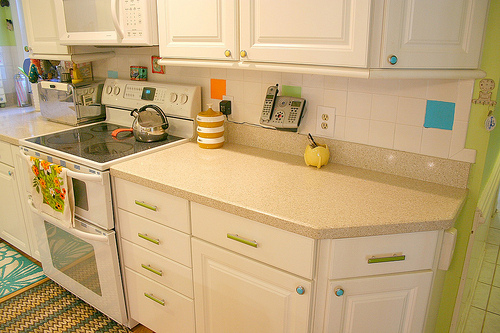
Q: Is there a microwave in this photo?
A: Yes, there is a microwave.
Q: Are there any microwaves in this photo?
A: Yes, there is a microwave.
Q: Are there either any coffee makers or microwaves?
A: Yes, there is a microwave.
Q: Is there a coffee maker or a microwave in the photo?
A: Yes, there is a microwave.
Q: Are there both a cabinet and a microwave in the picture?
A: Yes, there are both a microwave and a cabinet.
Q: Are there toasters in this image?
A: No, there are no toasters.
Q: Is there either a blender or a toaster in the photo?
A: No, there are no toasters or blenders.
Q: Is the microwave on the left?
A: Yes, the microwave is on the left of the image.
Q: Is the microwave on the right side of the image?
A: No, the microwave is on the left of the image.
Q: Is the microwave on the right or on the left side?
A: The microwave is on the left of the image.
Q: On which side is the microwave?
A: The microwave is on the left of the image.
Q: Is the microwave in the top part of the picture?
A: Yes, the microwave is in the top of the image.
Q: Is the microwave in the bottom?
A: No, the microwave is in the top of the image.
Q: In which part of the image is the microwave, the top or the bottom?
A: The microwave is in the top of the image.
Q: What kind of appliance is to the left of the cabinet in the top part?
A: The appliance is a microwave.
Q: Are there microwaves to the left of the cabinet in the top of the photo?
A: Yes, there is a microwave to the left of the cabinet.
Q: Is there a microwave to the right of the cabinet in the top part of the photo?
A: No, the microwave is to the left of the cabinet.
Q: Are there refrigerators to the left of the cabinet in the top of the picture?
A: No, there is a microwave to the left of the cabinet.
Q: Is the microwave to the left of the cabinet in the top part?
A: Yes, the microwave is to the left of the cabinet.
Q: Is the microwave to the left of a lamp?
A: No, the microwave is to the left of the cabinet.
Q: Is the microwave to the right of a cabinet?
A: No, the microwave is to the left of a cabinet.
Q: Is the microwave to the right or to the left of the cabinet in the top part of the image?
A: The microwave is to the left of the cabinet.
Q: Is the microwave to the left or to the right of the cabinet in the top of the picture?
A: The microwave is to the left of the cabinet.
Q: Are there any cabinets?
A: Yes, there is a cabinet.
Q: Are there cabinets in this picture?
A: Yes, there is a cabinet.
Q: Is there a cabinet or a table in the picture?
A: Yes, there is a cabinet.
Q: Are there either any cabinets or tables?
A: Yes, there is a cabinet.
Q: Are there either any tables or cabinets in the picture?
A: Yes, there is a cabinet.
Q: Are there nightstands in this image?
A: No, there are no nightstands.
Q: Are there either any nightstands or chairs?
A: No, there are no nightstands or chairs.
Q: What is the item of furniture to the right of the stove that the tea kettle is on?
A: The piece of furniture is a cabinet.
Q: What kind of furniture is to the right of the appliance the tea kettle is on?
A: The piece of furniture is a cabinet.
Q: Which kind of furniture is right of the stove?
A: The piece of furniture is a cabinet.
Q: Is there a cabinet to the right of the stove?
A: Yes, there is a cabinet to the right of the stove.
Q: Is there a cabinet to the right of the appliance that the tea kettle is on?
A: Yes, there is a cabinet to the right of the stove.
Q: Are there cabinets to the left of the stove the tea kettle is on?
A: No, the cabinet is to the right of the stove.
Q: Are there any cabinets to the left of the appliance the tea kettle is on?
A: No, the cabinet is to the right of the stove.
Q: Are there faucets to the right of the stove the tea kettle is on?
A: No, there is a cabinet to the right of the stove.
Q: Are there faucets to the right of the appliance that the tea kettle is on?
A: No, there is a cabinet to the right of the stove.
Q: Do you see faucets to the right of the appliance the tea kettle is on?
A: No, there is a cabinet to the right of the stove.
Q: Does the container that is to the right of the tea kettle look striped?
A: Yes, the container is striped.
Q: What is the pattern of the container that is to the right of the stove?
A: The container is striped.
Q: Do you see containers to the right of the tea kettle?
A: Yes, there is a container to the right of the tea kettle.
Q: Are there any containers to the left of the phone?
A: Yes, there is a container to the left of the phone.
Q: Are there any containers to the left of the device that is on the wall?
A: Yes, there is a container to the left of the phone.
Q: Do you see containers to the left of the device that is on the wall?
A: Yes, there is a container to the left of the phone.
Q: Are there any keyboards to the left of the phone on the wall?
A: No, there is a container to the left of the phone.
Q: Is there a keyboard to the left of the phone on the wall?
A: No, there is a container to the left of the phone.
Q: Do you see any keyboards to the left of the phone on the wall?
A: No, there is a container to the left of the phone.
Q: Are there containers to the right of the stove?
A: Yes, there is a container to the right of the stove.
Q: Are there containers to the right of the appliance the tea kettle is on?
A: Yes, there is a container to the right of the stove.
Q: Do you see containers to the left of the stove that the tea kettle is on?
A: No, the container is to the right of the stove.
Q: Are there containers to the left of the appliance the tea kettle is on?
A: No, the container is to the right of the stove.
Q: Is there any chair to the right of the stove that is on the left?
A: No, there is a container to the right of the stove.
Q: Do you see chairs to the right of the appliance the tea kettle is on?
A: No, there is a container to the right of the stove.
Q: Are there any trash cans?
A: No, there are no trash cans.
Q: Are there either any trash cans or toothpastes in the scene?
A: No, there are no trash cans or toothpastes.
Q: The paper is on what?
A: The paper is on the wall.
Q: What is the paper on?
A: The paper is on the wall.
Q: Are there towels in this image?
A: Yes, there is a towel.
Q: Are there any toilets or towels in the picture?
A: Yes, there is a towel.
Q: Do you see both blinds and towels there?
A: No, there is a towel but no blinds.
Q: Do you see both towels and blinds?
A: No, there is a towel but no blinds.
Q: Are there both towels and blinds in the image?
A: No, there is a towel but no blinds.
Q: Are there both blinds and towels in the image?
A: No, there is a towel but no blinds.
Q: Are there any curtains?
A: No, there are no curtains.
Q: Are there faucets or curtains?
A: No, there are no curtains or faucets.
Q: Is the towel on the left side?
A: Yes, the towel is on the left of the image.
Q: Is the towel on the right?
A: No, the towel is on the left of the image.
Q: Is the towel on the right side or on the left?
A: The towel is on the left of the image.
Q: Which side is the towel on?
A: The towel is on the left of the image.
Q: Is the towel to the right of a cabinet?
A: No, the towel is to the left of a cabinet.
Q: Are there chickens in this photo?
A: No, there are no chickens.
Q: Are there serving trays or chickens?
A: No, there are no chickens or serving trays.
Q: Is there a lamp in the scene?
A: No, there are no lamps.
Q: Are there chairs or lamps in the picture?
A: No, there are no lamps or chairs.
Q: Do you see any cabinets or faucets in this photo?
A: Yes, there is a cabinet.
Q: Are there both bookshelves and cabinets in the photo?
A: No, there is a cabinet but no bookshelves.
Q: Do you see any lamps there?
A: No, there are no lamps.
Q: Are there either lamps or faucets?
A: No, there are no lamps or faucets.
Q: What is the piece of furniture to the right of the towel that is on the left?
A: The piece of furniture is a cabinet.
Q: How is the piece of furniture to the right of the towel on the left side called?
A: The piece of furniture is a cabinet.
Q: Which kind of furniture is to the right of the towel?
A: The piece of furniture is a cabinet.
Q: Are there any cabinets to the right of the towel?
A: Yes, there is a cabinet to the right of the towel.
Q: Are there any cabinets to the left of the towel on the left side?
A: No, the cabinet is to the right of the towel.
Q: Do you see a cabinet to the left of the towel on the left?
A: No, the cabinet is to the right of the towel.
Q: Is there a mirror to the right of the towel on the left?
A: No, there is a cabinet to the right of the towel.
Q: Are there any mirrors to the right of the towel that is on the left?
A: No, there is a cabinet to the right of the towel.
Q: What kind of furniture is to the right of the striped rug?
A: The piece of furniture is a cabinet.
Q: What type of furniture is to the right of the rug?
A: The piece of furniture is a cabinet.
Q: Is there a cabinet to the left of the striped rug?
A: No, the cabinet is to the right of the rug.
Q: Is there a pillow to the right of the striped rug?
A: No, there is a cabinet to the right of the rug.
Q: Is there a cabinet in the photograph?
A: Yes, there is a cabinet.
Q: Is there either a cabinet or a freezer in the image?
A: Yes, there is a cabinet.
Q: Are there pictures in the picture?
A: No, there are no pictures.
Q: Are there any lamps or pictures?
A: No, there are no pictures or lamps.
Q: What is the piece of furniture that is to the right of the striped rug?
A: The piece of furniture is a cabinet.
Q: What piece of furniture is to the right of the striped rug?
A: The piece of furniture is a cabinet.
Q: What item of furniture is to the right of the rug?
A: The piece of furniture is a cabinet.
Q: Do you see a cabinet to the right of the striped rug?
A: Yes, there is a cabinet to the right of the rug.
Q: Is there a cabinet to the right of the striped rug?
A: Yes, there is a cabinet to the right of the rug.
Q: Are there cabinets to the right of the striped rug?
A: Yes, there is a cabinet to the right of the rug.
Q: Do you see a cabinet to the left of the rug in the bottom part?
A: No, the cabinet is to the right of the rug.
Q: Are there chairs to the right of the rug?
A: No, there is a cabinet to the right of the rug.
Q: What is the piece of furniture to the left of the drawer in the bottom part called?
A: The piece of furniture is a cabinet.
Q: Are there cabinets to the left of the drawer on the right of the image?
A: Yes, there is a cabinet to the left of the drawer.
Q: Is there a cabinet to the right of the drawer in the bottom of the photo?
A: No, the cabinet is to the left of the drawer.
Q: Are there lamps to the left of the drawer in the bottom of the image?
A: No, there is a cabinet to the left of the drawer.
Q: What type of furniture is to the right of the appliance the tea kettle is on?
A: The piece of furniture is a cabinet.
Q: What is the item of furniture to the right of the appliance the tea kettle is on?
A: The piece of furniture is a cabinet.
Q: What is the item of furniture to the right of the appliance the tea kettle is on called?
A: The piece of furniture is a cabinet.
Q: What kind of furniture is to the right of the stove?
A: The piece of furniture is a cabinet.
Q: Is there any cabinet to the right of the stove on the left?
A: Yes, there is a cabinet to the right of the stove.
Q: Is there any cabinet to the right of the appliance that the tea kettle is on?
A: Yes, there is a cabinet to the right of the stove.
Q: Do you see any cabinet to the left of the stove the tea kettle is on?
A: No, the cabinet is to the right of the stove.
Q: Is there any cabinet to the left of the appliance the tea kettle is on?
A: No, the cabinet is to the right of the stove.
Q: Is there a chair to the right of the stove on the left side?
A: No, there is a cabinet to the right of the stove.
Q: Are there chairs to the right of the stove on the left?
A: No, there is a cabinet to the right of the stove.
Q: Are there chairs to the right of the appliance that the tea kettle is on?
A: No, there is a cabinet to the right of the stove.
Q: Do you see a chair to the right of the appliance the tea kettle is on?
A: No, there is a cabinet to the right of the stove.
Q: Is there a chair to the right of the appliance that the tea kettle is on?
A: No, there is a cabinet to the right of the stove.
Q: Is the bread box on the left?
A: Yes, the bread box is on the left of the image.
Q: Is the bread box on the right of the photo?
A: No, the bread box is on the left of the image.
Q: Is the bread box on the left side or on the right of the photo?
A: The bread box is on the left of the image.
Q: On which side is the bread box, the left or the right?
A: The bread box is on the left of the image.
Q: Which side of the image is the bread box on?
A: The bread box is on the left of the image.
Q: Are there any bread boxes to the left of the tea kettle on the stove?
A: Yes, there is a bread box to the left of the tea kettle.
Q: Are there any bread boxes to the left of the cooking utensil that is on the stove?
A: Yes, there is a bread box to the left of the tea kettle.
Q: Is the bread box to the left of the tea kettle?
A: Yes, the bread box is to the left of the tea kettle.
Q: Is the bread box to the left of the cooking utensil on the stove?
A: Yes, the bread box is to the left of the tea kettle.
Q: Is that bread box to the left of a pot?
A: No, the bread box is to the left of the tea kettle.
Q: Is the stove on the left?
A: Yes, the stove is on the left of the image.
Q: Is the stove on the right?
A: No, the stove is on the left of the image.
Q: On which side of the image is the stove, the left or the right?
A: The stove is on the left of the image.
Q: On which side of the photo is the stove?
A: The stove is on the left of the image.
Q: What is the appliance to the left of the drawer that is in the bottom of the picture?
A: The appliance is a stove.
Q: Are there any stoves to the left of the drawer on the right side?
A: Yes, there is a stove to the left of the drawer.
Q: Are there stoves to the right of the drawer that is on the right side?
A: No, the stove is to the left of the drawer.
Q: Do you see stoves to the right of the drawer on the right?
A: No, the stove is to the left of the drawer.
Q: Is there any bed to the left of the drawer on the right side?
A: No, there is a stove to the left of the drawer.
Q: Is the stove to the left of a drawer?
A: Yes, the stove is to the left of a drawer.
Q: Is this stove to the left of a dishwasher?
A: No, the stove is to the left of a drawer.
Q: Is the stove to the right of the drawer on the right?
A: No, the stove is to the left of the drawer.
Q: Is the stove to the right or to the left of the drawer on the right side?
A: The stove is to the left of the drawer.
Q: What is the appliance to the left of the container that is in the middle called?
A: The appliance is a stove.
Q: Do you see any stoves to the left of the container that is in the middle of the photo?
A: Yes, there is a stove to the left of the container.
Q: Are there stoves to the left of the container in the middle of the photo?
A: Yes, there is a stove to the left of the container.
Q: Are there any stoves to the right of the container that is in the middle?
A: No, the stove is to the left of the container.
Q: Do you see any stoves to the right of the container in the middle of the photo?
A: No, the stove is to the left of the container.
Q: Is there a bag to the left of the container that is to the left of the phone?
A: No, there is a stove to the left of the container.